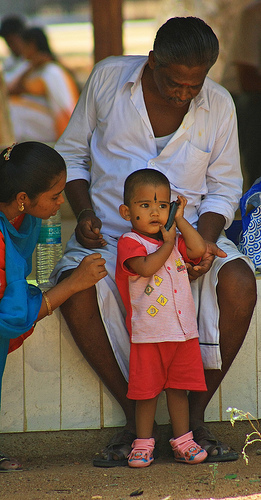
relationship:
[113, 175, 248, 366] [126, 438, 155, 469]
baby wearing shoes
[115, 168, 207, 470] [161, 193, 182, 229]
baby is on phone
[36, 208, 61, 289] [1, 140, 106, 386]
bottle near girl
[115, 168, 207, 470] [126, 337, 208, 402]
baby wearing shorts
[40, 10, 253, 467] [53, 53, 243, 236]
man wearing shirt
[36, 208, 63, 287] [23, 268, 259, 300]
bottle on ledge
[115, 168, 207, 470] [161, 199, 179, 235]
baby on phone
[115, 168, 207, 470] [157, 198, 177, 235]
baby on phone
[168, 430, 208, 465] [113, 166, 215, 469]
shoe on child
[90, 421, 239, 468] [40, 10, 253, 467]
feet on man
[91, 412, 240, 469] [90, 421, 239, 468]
sandals on feet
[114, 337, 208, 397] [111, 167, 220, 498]
shorts on child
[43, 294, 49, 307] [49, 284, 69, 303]
bracelet on arm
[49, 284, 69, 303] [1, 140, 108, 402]
arm on girl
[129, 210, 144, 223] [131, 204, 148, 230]
marking on cheek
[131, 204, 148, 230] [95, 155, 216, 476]
cheek on child